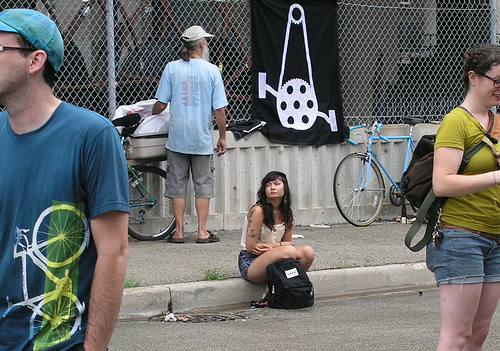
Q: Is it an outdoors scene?
A: Yes, it is outdoors.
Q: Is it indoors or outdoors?
A: It is outdoors.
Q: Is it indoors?
A: No, it is outdoors.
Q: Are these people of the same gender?
A: No, they are both male and female.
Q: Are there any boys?
A: No, there are no boys.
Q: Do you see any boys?
A: No, there are no boys.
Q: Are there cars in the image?
A: No, there are no cars.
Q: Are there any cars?
A: No, there are no cars.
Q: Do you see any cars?
A: No, there are no cars.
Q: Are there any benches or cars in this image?
A: No, there are no cars or benches.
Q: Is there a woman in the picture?
A: Yes, there is a woman.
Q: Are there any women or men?
A: Yes, there is a woman.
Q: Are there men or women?
A: Yes, there is a woman.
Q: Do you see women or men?
A: Yes, there is a woman.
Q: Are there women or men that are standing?
A: Yes, the woman is standing.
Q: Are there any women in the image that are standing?
A: Yes, there is a woman that is standing.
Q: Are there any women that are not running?
A: Yes, there is a woman that is standing.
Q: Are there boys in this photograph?
A: No, there are no boys.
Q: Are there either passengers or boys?
A: No, there are no boys or passengers.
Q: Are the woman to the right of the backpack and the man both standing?
A: Yes, both the woman and the man are standing.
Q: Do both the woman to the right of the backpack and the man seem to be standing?
A: Yes, both the woman and the man are standing.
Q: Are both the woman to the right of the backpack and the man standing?
A: Yes, both the woman and the man are standing.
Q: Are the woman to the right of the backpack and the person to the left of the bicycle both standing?
A: Yes, both the woman and the man are standing.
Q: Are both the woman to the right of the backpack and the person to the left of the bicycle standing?
A: Yes, both the woman and the man are standing.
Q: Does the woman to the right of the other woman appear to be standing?
A: Yes, the woman is standing.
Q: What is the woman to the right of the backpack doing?
A: The woman is standing.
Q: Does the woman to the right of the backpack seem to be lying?
A: No, the woman is standing.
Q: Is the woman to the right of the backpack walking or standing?
A: The woman is standing.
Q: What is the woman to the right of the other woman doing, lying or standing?
A: The woman is standing.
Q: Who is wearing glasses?
A: The woman is wearing glasses.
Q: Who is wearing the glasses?
A: The woman is wearing glasses.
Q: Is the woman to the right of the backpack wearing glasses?
A: Yes, the woman is wearing glasses.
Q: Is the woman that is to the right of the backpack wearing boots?
A: No, the woman is wearing glasses.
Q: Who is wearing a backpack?
A: The woman is wearing a backpack.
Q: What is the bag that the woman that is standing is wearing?
A: The bag is a backpack.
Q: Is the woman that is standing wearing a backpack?
A: Yes, the woman is wearing a backpack.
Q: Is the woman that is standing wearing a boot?
A: No, the woman is wearing a backpack.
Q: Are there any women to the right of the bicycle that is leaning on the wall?
A: Yes, there is a woman to the right of the bicycle.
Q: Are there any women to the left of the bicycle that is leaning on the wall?
A: No, the woman is to the right of the bicycle.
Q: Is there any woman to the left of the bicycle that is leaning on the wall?
A: No, the woman is to the right of the bicycle.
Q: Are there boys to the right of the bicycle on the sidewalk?
A: No, there is a woman to the right of the bicycle.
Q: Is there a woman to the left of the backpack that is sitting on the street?
A: No, the woman is to the right of the backpack.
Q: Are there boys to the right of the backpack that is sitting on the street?
A: No, there is a woman to the right of the backpack.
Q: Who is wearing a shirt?
A: The woman is wearing a shirt.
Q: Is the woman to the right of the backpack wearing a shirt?
A: Yes, the woman is wearing a shirt.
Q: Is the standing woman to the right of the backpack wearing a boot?
A: No, the woman is wearing a shirt.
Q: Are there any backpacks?
A: Yes, there is a backpack.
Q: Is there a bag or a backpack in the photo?
A: Yes, there is a backpack.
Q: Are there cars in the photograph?
A: No, there are no cars.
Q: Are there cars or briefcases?
A: No, there are no cars or briefcases.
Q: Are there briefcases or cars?
A: No, there are no cars or briefcases.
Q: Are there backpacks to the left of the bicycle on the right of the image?
A: No, the backpack is to the right of the bicycle.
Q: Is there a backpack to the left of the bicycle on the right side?
A: No, the backpack is to the right of the bicycle.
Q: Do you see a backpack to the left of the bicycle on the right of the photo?
A: No, the backpack is to the right of the bicycle.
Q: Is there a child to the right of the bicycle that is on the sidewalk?
A: No, there is a backpack to the right of the bicycle.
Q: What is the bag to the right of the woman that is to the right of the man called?
A: The bag is a backpack.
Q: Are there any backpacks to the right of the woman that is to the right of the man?
A: Yes, there is a backpack to the right of the woman.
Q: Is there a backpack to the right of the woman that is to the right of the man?
A: Yes, there is a backpack to the right of the woman.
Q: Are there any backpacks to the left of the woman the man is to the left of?
A: No, the backpack is to the right of the woman.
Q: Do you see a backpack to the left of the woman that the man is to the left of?
A: No, the backpack is to the right of the woman.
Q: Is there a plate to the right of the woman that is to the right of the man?
A: No, there is a backpack to the right of the woman.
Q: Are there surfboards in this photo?
A: No, there are no surfboards.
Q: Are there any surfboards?
A: No, there are no surfboards.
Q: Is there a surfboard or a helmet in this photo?
A: No, there are no surfboards or helmets.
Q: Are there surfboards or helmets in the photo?
A: No, there are no surfboards or helmets.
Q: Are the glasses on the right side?
A: Yes, the glasses are on the right of the image.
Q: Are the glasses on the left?
A: No, the glasses are on the right of the image.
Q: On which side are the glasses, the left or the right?
A: The glasses are on the right of the image.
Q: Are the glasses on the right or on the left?
A: The glasses are on the right of the image.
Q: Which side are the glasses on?
A: The glasses are on the right of the image.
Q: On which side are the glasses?
A: The glasses are on the right of the image.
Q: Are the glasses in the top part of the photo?
A: Yes, the glasses are in the top of the image.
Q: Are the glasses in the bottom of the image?
A: No, the glasses are in the top of the image.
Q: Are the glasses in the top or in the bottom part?
A: The glasses are in the top of the image.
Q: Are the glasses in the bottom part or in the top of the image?
A: The glasses are in the top of the image.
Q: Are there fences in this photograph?
A: Yes, there is a fence.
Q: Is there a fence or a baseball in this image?
A: Yes, there is a fence.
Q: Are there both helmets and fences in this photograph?
A: No, there is a fence but no helmets.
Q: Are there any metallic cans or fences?
A: Yes, there is a metal fence.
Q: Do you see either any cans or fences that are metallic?
A: Yes, the fence is metallic.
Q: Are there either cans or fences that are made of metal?
A: Yes, the fence is made of metal.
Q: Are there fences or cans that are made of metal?
A: Yes, the fence is made of metal.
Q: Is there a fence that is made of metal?
A: Yes, there is a fence that is made of metal.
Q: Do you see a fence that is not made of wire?
A: Yes, there is a fence that is made of metal.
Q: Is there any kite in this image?
A: No, there are no kites.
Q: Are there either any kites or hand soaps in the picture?
A: No, there are no kites or hand soaps.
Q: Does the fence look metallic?
A: Yes, the fence is metallic.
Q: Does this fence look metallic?
A: Yes, the fence is metallic.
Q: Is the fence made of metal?
A: Yes, the fence is made of metal.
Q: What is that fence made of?
A: The fence is made of metal.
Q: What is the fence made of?
A: The fence is made of metal.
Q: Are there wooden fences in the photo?
A: No, there is a fence but it is metallic.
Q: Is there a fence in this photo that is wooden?
A: No, there is a fence but it is metallic.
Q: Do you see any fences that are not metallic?
A: No, there is a fence but it is metallic.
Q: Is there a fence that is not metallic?
A: No, there is a fence but it is metallic.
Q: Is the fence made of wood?
A: No, the fence is made of metal.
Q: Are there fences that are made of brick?
A: No, there is a fence but it is made of metal.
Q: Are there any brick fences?
A: No, there is a fence but it is made of metal.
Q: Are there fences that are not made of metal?
A: No, there is a fence but it is made of metal.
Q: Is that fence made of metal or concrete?
A: The fence is made of metal.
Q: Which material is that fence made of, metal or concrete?
A: The fence is made of metal.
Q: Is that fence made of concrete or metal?
A: The fence is made of metal.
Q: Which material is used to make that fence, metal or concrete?
A: The fence is made of metal.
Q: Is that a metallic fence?
A: Yes, that is a metallic fence.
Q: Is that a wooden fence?
A: No, that is a metallic fence.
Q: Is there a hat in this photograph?
A: Yes, there is a hat.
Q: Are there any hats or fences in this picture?
A: Yes, there is a hat.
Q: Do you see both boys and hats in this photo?
A: No, there is a hat but no boys.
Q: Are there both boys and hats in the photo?
A: No, there is a hat but no boys.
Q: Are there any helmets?
A: No, there are no helmets.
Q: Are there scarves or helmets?
A: No, there are no helmets or scarves.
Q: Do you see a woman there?
A: Yes, there is a woman.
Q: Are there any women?
A: Yes, there is a woman.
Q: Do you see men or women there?
A: Yes, there is a woman.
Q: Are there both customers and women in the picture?
A: No, there is a woman but no customers.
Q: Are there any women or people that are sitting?
A: Yes, the woman is sitting.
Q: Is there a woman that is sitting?
A: Yes, there is a woman that is sitting.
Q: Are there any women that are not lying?
A: Yes, there is a woman that is sitting.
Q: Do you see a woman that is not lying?
A: Yes, there is a woman that is sitting .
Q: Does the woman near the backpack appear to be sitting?
A: Yes, the woman is sitting.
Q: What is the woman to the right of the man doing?
A: The woman is sitting.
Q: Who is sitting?
A: The woman is sitting.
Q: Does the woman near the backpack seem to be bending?
A: No, the woman is sitting.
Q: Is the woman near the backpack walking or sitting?
A: The woman is sitting.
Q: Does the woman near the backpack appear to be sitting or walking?
A: The woman is sitting.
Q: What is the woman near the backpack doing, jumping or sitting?
A: The woman is sitting.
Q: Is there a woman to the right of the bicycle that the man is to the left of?
A: Yes, there is a woman to the right of the bicycle.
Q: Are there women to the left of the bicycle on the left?
A: No, the woman is to the right of the bicycle.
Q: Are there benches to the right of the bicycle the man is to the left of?
A: No, there is a woman to the right of the bicycle.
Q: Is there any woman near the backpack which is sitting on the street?
A: Yes, there is a woman near the backpack.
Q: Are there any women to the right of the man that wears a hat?
A: Yes, there is a woman to the right of the man.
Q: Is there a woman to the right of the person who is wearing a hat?
A: Yes, there is a woman to the right of the man.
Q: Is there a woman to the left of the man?
A: No, the woman is to the right of the man.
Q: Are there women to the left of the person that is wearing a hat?
A: No, the woman is to the right of the man.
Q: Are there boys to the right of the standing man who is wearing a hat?
A: No, there is a woman to the right of the man.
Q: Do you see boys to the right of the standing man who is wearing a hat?
A: No, there is a woman to the right of the man.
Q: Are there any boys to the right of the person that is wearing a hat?
A: No, there is a woman to the right of the man.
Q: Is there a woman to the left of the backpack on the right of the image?
A: Yes, there is a woman to the left of the backpack.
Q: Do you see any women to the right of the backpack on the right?
A: No, the woman is to the left of the backpack.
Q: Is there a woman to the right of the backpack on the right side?
A: No, the woman is to the left of the backpack.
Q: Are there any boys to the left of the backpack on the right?
A: No, there is a woman to the left of the backpack.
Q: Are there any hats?
A: Yes, there is a hat.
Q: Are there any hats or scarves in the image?
A: Yes, there is a hat.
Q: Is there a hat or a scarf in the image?
A: Yes, there is a hat.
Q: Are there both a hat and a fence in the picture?
A: Yes, there are both a hat and a fence.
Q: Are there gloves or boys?
A: No, there are no boys or gloves.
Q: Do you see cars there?
A: No, there are no cars.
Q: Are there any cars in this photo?
A: No, there are no cars.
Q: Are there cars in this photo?
A: No, there are no cars.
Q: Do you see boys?
A: No, there are no boys.